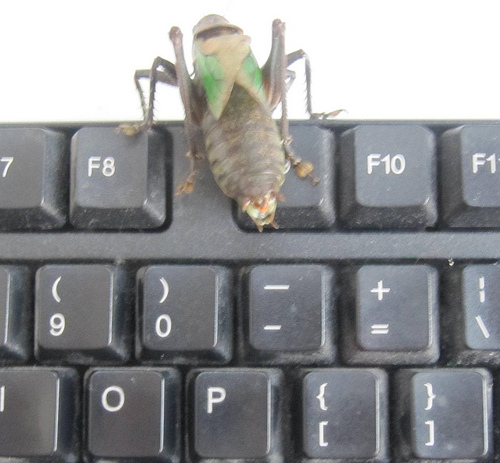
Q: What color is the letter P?
A: White.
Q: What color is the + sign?
A: White.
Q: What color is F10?
A: White.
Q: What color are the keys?
A: Black.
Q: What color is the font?
A: White.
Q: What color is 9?
A: White.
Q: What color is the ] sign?
A: White.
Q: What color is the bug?
A: Brown.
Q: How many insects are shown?
A: 1.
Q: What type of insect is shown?
A: Grasshopper.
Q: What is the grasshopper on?
A: Keyboard.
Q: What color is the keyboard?
A: Gray/white.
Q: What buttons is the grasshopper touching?
A: F8 and F9.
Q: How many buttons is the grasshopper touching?
A: 2.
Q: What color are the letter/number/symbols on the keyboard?
A: White.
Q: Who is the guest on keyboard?
A: An unwanted guest.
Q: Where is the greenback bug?
A: On typewriter keyboard.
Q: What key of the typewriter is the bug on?
A: F9.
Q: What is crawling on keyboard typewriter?
A: A bug.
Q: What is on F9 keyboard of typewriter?
A: Green backed insect.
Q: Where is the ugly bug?
A: On typewriter keyboard.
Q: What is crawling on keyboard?
A: Grasshopper.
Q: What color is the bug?
A: Green and brown.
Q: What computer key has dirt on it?
A: Black plastic P key.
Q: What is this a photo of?
A: Part of a keyboard.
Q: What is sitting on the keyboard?
A: A bug.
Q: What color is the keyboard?
A: Black.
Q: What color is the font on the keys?
A: White.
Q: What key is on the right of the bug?
A: F10.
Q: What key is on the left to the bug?
A: F8.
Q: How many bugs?
A: 1.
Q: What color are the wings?
A: Green.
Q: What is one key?
A: F10.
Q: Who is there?
A: No one.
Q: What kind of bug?
A: Cricket.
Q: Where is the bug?
A: On top.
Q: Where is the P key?
A: The bottom.